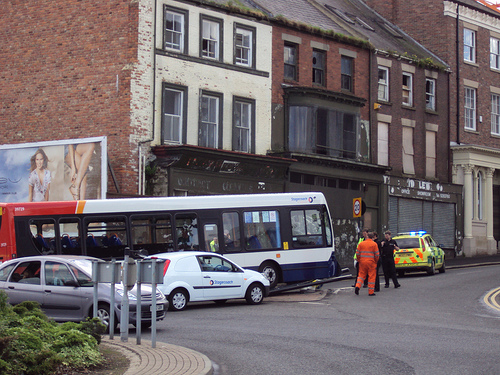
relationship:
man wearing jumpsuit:
[350, 230, 381, 298] [350, 240, 380, 296]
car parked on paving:
[390, 229, 447, 277] [208, 302, 423, 359]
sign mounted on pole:
[90, 259, 121, 286] [90, 258, 99, 321]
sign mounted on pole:
[90, 259, 121, 286] [107, 256, 116, 338]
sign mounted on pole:
[120, 258, 138, 290] [118, 253, 129, 342]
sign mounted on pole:
[135, 255, 165, 285] [133, 259, 142, 345]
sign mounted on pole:
[135, 255, 165, 285] [149, 258, 158, 348]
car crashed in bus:
[124, 240, 268, 308] [1, 191, 337, 285]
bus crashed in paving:
[1, 191, 337, 285] [208, 302, 423, 359]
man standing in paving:
[353, 231, 379, 297] [208, 302, 423, 359]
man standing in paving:
[376, 231, 402, 289] [208, 302, 423, 359]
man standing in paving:
[350, 230, 378, 288] [208, 302, 423, 359]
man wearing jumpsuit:
[353, 231, 379, 297] [351, 235, 380, 295]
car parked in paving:
[390, 229, 447, 277] [208, 302, 423, 359]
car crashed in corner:
[124, 240, 268, 308] [1, 272, 318, 372]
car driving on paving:
[0, 255, 169, 330] [208, 302, 423, 359]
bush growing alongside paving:
[1, 330, 64, 373] [208, 302, 423, 359]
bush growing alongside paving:
[20, 311, 59, 334] [208, 302, 423, 359]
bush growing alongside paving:
[53, 340, 105, 370] [208, 302, 423, 359]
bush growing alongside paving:
[74, 313, 107, 346] [208, 302, 423, 359]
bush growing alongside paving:
[10, 296, 38, 318] [208, 302, 423, 359]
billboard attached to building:
[0, 133, 109, 200] [3, 1, 463, 264]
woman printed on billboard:
[25, 148, 54, 200] [0, 133, 109, 200]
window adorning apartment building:
[159, 80, 184, 146] [1, 1, 296, 238]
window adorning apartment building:
[198, 91, 220, 147] [1, 1, 296, 238]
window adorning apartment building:
[232, 97, 253, 154] [1, 1, 296, 238]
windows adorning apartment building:
[149, 1, 263, 73] [1, 1, 296, 238]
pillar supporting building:
[459, 162, 476, 257] [361, 1, 482, 259]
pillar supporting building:
[481, 166, 484, 252] [361, 1, 482, 259]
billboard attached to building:
[0, 133, 109, 236] [3, 1, 463, 264]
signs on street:
[61, 256, 169, 340] [194, 311, 387, 368]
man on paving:
[353, 231, 379, 297] [208, 302, 423, 359]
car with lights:
[390, 229, 447, 277] [395, 230, 434, 254]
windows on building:
[149, 8, 256, 120] [47, 16, 471, 267]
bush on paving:
[65, 318, 104, 358] [208, 302, 423, 359]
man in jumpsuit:
[346, 237, 396, 283] [355, 240, 390, 294]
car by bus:
[124, 240, 268, 308] [18, 197, 363, 297]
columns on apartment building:
[442, 158, 496, 238] [1, 0, 499, 280]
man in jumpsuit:
[353, 231, 379, 297] [344, 240, 388, 284]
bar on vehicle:
[375, 232, 439, 266] [388, 232, 478, 277]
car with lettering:
[124, 240, 268, 308] [212, 279, 233, 284]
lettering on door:
[212, 279, 233, 284] [201, 273, 243, 295]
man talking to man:
[350, 231, 379, 293] [380, 232, 399, 291]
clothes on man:
[353, 238, 379, 293] [353, 229, 378, 295]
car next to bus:
[124, 240, 268, 308] [1, 191, 337, 285]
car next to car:
[0, 255, 169, 330] [124, 240, 268, 308]